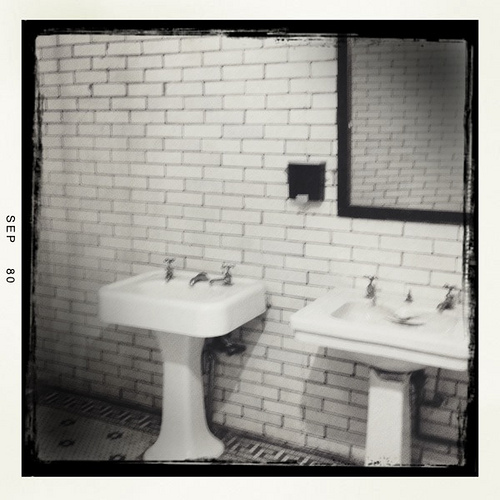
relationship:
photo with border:
[35, 34, 466, 466] [26, 460, 479, 477]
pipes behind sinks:
[410, 375, 464, 455] [96, 258, 276, 463]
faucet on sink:
[161, 255, 176, 285] [97, 266, 268, 336]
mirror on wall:
[344, 42, 466, 211] [27, 36, 467, 466]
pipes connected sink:
[208, 340, 253, 410] [97, 258, 269, 338]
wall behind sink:
[27, 36, 467, 466] [287, 269, 471, 472]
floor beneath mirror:
[27, 372, 367, 468] [335, 37, 480, 224]